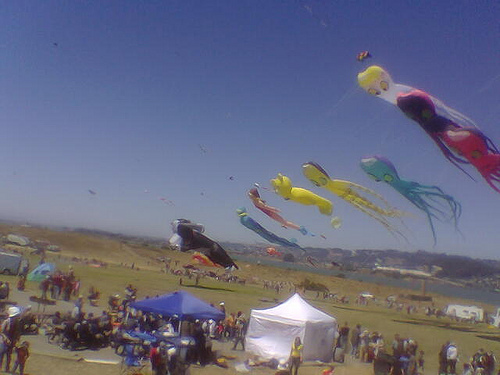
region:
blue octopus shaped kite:
[353, 155, 469, 226]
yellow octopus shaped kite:
[301, 158, 402, 226]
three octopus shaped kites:
[346, 51, 491, 162]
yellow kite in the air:
[268, 170, 341, 225]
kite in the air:
[235, 212, 308, 257]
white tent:
[248, 285, 338, 362]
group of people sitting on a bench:
[51, 287, 116, 351]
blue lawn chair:
[118, 344, 145, 374]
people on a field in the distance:
[244, 278, 425, 305]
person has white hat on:
[1, 303, 25, 349]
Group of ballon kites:
[166, 62, 496, 273]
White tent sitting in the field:
[244, 291, 335, 368]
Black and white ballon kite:
[166, 216, 238, 271]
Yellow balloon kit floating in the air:
[266, 171, 334, 214]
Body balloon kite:
[352, 62, 497, 190]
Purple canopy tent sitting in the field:
[126, 290, 227, 320]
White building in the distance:
[445, 301, 480, 323]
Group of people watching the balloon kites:
[37, 268, 247, 363]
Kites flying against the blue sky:
[0, 0, 497, 261]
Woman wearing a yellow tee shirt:
[284, 335, 308, 372]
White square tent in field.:
[247, 295, 337, 371]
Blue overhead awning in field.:
[122, 288, 225, 345]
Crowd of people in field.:
[4, 299, 125, 355]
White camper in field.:
[441, 305, 484, 325]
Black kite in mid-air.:
[165, 212, 232, 275]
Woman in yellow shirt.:
[282, 337, 309, 374]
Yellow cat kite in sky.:
[267, 172, 335, 214]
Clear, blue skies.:
[39, 128, 207, 209]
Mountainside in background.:
[318, 246, 498, 279]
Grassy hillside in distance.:
[42, 224, 153, 265]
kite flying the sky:
[358, 68, 485, 134]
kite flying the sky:
[397, 88, 498, 173]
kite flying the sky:
[360, 155, 471, 234]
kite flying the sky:
[300, 160, 410, 239]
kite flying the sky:
[267, 173, 338, 218]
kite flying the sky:
[248, 186, 312, 231]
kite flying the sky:
[234, 210, 294, 250]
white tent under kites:
[245, 292, 337, 359]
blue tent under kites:
[123, 290, 222, 351]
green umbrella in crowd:
[27, 260, 52, 282]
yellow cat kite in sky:
[268, 170, 340, 217]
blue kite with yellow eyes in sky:
[360, 152, 461, 242]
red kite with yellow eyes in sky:
[446, 127, 499, 205]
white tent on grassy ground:
[239, 290, 343, 364]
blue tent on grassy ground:
[123, 290, 223, 349]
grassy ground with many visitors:
[7, 243, 499, 366]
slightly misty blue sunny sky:
[12, 0, 494, 262]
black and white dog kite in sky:
[168, 205, 246, 272]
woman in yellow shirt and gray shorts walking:
[287, 333, 307, 371]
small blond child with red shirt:
[13, 336, 32, 371]